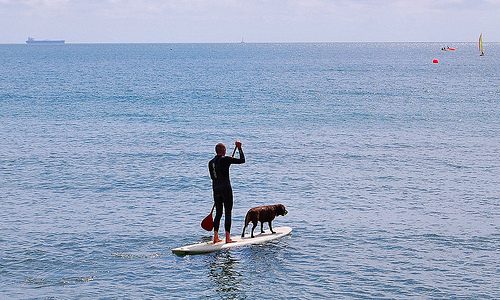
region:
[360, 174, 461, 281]
the water is blue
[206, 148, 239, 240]
a person standing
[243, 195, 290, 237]
a dog that is brown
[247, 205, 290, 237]
a dog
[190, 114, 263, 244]
man on the board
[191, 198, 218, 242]
top part of the paddle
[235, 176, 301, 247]
dog on the board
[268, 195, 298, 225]
head of the dog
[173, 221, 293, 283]
white board in water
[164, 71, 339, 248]
one man and one dog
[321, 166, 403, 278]
water next to board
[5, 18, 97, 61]
boat in the distance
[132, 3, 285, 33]
sky above the water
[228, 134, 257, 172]
arm of the man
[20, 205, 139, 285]
Section of the ocean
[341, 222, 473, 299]
Section of the ocean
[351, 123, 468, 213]
Section of the ocean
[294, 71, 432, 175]
Section of the ocean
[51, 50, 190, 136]
Section of the ocean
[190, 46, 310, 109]
Section of the ocean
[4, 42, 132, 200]
Section of the ocean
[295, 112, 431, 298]
Section of the ocean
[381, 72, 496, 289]
Section of the ocean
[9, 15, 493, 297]
a scene during the day time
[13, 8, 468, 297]
an image outside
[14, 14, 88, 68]
a ship in the background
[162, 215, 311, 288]
a white surfboard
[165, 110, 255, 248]
a person with an oar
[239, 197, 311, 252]
a brown dog on a surfboard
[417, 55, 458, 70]
a red balloon on the water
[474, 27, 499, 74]
a yellow on the windboard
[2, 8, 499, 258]
a place to swim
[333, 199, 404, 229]
calm blue waters in the ocean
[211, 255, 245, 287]
paddle's shadow on the water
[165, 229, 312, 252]
white surf board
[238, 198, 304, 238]
dog standing on the surf board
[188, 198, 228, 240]
red paddle in man's hand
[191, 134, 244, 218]
surfer standing on surf board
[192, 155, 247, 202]
man wearing surf suit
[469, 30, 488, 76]
small boat in the horizon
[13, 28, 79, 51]
large ship on the water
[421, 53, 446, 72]
red buoy on the water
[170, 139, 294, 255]
Man and dog on paddleboard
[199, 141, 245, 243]
Man in black wetsuit holding paddle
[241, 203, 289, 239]
Large brown dog standing on paddleboard